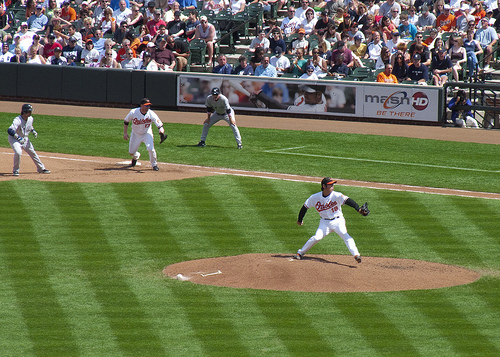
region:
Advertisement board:
[246, 82, 441, 119]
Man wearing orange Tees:
[377, 64, 397, 81]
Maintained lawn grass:
[21, 197, 156, 300]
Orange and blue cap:
[321, 175, 335, 187]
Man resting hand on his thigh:
[197, 90, 240, 149]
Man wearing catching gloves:
[158, 130, 168, 142]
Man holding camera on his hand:
[448, 89, 480, 127]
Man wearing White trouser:
[312, 223, 363, 262]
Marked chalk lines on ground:
[218, 165, 297, 182]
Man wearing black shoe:
[153, 163, 161, 170]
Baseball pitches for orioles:
[292, 176, 368, 266]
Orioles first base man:
[117, 95, 172, 172]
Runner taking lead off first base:
[9, 101, 51, 183]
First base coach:
[200, 82, 244, 152]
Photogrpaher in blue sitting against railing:
[447, 86, 480, 125]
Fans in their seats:
[0, 1, 498, 85]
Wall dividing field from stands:
[2, 62, 444, 126]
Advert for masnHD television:
[175, 72, 442, 122]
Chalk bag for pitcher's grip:
[174, 272, 182, 280]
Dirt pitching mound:
[166, 249, 480, 291]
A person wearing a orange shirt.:
[377, 61, 399, 83]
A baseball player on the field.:
[292, 173, 371, 263]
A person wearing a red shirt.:
[43, 30, 65, 57]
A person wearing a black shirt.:
[448, 35, 468, 70]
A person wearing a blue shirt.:
[394, 10, 418, 40]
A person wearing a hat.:
[192, 14, 221, 64]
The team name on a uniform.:
[313, 198, 340, 214]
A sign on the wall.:
[176, 72, 438, 123]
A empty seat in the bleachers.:
[245, 0, 265, 26]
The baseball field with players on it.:
[1, 86, 498, 354]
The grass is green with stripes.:
[45, 195, 167, 252]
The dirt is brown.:
[250, 262, 341, 293]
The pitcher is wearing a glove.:
[355, 197, 376, 223]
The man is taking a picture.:
[447, 85, 482, 140]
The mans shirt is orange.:
[378, 60, 399, 86]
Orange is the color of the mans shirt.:
[361, 58, 402, 89]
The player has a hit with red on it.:
[132, 93, 167, 108]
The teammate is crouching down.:
[186, 76, 251, 138]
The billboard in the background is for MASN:
[162, 65, 438, 122]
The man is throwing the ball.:
[258, 167, 397, 262]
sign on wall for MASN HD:
[170, 67, 446, 124]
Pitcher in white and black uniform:
[284, 173, 369, 275]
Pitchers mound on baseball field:
[162, 241, 489, 307]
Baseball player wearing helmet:
[6, 100, 52, 175]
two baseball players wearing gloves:
[122, 99, 372, 266]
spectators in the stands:
[2, 2, 497, 104]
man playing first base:
[105, 97, 170, 177]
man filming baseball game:
[447, 86, 484, 134]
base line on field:
[3, 143, 498, 204]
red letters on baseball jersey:
[132, 114, 153, 128]